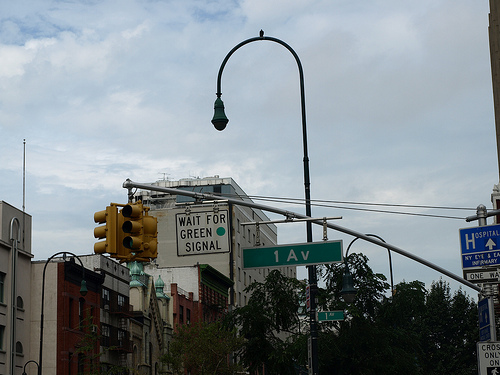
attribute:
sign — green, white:
[241, 240, 346, 268]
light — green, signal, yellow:
[120, 200, 146, 263]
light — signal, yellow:
[92, 201, 120, 256]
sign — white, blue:
[456, 224, 500, 270]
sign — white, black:
[176, 212, 233, 258]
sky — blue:
[2, 0, 498, 297]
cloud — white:
[6, 32, 146, 90]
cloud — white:
[43, 150, 278, 192]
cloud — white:
[344, 171, 464, 227]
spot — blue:
[5, 16, 34, 30]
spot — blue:
[34, 25, 64, 41]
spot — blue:
[10, 37, 31, 46]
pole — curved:
[208, 28, 331, 373]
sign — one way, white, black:
[461, 266, 500, 286]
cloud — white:
[244, 2, 499, 56]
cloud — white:
[138, 2, 259, 34]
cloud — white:
[153, 68, 300, 116]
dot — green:
[214, 225, 227, 237]